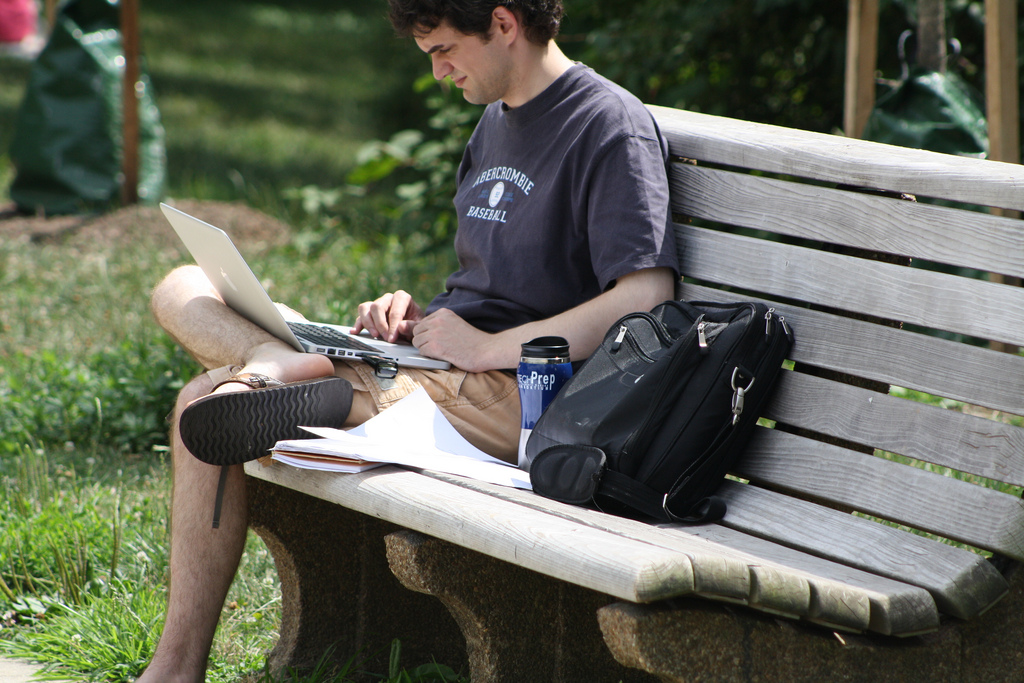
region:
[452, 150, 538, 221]
The design and names on the man's t-shirt.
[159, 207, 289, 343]
The lid of the laptop on the man's lap.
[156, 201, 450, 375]
The laptop on the man's lap.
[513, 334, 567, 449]
The thermus cup next to the man.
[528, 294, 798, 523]
The black book bag on the bench.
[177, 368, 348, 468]
The man's flip flop sandal on his foot.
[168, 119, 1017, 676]
The bench the man is sitting on.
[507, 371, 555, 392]
The white lettering on the thermus cup next to the man.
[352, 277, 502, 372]
The man's hands resting on the laptop.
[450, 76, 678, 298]
The t-shirt the man is wearing.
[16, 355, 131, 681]
Grass is green color.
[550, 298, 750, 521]
bag is in bench.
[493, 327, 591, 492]
Coffee mug is blue and black color.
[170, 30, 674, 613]
man is sitting in the bench.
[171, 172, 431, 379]
laptop is grey color.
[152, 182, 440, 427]
Laptop is in the man lap.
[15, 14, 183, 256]
Trash is green color.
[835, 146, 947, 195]
wood on the bench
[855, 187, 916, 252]
wood on the bench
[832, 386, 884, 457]
wood on the bench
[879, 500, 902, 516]
wood on the bench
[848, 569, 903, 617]
wood on the bench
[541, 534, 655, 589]
wood on the bench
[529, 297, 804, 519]
Black backpack on a bench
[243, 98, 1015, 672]
A wood bench outdoors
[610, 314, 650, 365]
A zipper on a backpack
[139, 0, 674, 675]
A guy sitting on a bench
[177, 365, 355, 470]
Flip flops on a man's foot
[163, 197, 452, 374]
A silver laptop on a man's lap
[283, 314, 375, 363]
A keyboard on a laptop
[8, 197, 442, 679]
Green grass near a bench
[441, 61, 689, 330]
A shirt on a man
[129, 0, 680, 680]
A person is sitting down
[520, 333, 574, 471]
A bottle for holding liquid.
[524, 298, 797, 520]
A bag for holding things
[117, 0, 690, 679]
man who is wearing khaki shorts and dark blue shirt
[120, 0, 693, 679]
man who is deeply engrossed in his laptop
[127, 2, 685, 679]
man sitting on a wooden park bench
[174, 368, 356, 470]
flip flop on the mans foot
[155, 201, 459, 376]
laptop on the mans lap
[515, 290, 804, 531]
mans black back pack sitting next to himon the bench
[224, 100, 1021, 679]
bench the man is sitting on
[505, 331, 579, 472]
glass sitting next to the man on the bench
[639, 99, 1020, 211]
wooden slat of the bench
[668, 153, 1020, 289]
wooden slat of the bench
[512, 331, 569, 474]
blue and gray travel mug with black lid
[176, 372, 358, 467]
brown leather thong sandals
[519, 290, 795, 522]
black backpack with silver zippers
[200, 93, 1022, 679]
light gray wooden park bench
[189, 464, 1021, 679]
cement legs of a gray bench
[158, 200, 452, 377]
white open laptop with black keyboard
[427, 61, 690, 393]
blue tee shirt with white letters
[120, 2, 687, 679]
man sitting with right leg crossed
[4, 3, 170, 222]
large green trash bag behind a post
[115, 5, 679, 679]
a person is sitting down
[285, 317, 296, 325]
a key on a keyboard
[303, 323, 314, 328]
a key on a keyboard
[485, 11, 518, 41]
the ear of the man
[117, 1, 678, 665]
the man is sitting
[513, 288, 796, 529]
the bag is black